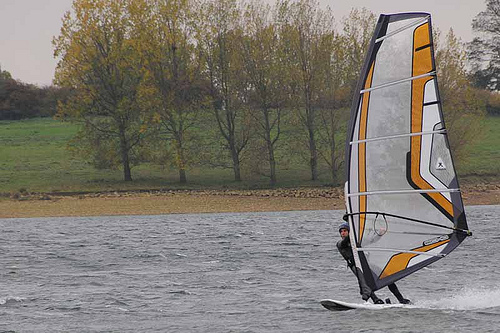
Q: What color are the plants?
A: Green.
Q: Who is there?
A: A person.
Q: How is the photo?
A: Clear.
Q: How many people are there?
A: One.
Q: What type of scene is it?
A: Outdoor.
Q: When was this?
A: Daytime.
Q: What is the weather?
A: Sunny.